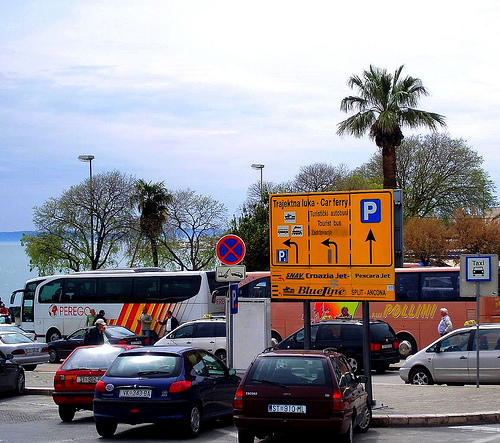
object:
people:
[83, 308, 96, 325]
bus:
[9, 265, 167, 339]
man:
[82, 318, 107, 346]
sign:
[271, 187, 403, 301]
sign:
[215, 232, 247, 264]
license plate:
[119, 389, 151, 398]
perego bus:
[33, 269, 229, 343]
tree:
[20, 170, 129, 272]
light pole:
[89, 160, 96, 257]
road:
[0, 363, 499, 441]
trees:
[402, 215, 452, 265]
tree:
[230, 183, 268, 271]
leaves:
[418, 136, 455, 169]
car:
[47, 324, 149, 361]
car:
[0, 322, 37, 343]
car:
[0, 350, 27, 398]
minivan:
[398, 318, 499, 385]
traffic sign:
[214, 232, 246, 314]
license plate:
[267, 403, 306, 414]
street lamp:
[77, 155, 96, 258]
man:
[437, 306, 454, 347]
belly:
[436, 318, 447, 334]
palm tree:
[335, 62, 447, 189]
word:
[48, 302, 94, 316]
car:
[0, 330, 52, 372]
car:
[153, 313, 227, 368]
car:
[52, 342, 143, 427]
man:
[154, 305, 182, 341]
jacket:
[157, 315, 179, 331]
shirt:
[165, 317, 173, 331]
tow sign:
[213, 264, 246, 280]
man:
[333, 305, 351, 321]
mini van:
[271, 317, 399, 373]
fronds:
[336, 64, 446, 132]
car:
[224, 338, 416, 441]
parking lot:
[0, 283, 498, 441]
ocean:
[0, 242, 221, 307]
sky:
[0, 1, 498, 228]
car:
[92, 342, 244, 440]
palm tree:
[128, 178, 175, 267]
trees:
[174, 187, 229, 270]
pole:
[259, 166, 264, 203]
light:
[250, 163, 265, 170]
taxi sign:
[465, 256, 491, 283]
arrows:
[282, 236, 299, 263]